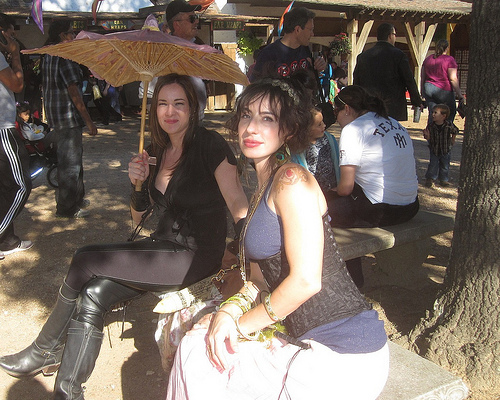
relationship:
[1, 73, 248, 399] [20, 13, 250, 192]
woman holding umbrella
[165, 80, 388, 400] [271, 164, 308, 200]
woman has tattoo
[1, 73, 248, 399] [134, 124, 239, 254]
woman wearing blouse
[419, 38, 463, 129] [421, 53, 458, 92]
woman wearing shirt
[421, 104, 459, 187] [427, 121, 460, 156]
boy wearing shirt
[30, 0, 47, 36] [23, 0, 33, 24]
flag hanging from pole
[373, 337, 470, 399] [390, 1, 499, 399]
bench next to tree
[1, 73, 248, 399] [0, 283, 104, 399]
woman wearing boots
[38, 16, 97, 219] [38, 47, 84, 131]
man wearing shirt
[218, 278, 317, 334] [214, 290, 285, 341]
forearms covered in bracelets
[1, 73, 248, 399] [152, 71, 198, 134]
woman has head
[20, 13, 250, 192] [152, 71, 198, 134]
umbrella over head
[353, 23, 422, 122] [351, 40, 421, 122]
man wearing suit jacket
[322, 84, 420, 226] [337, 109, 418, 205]
woman wearing shirt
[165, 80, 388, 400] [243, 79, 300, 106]
woman wearing headband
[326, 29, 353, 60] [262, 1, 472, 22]
flowers hanging from awning